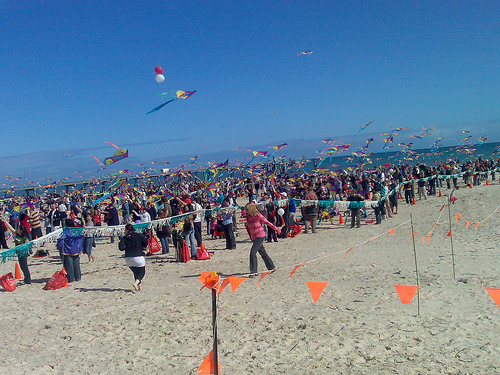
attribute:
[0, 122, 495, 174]
kites — many, flying, airborne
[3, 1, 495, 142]
sky — cloudy, blue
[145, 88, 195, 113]
kite — colorful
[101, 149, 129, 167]
kite — colorful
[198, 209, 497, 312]
flag — orange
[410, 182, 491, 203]
cone — orange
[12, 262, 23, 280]
cone — orange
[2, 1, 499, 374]
tree — non-existant, non-existent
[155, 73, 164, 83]
balloon — white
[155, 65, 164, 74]
balloon — red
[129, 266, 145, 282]
pants — black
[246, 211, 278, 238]
shirt — pink, striped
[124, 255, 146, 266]
under-shirt — white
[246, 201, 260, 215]
hair — blond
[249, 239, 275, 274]
pants — gray